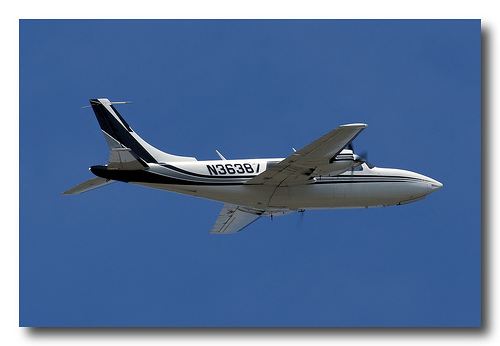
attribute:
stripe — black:
[148, 180, 411, 187]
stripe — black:
[162, 156, 419, 178]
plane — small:
[62, 95, 447, 239]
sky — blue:
[157, 47, 442, 108]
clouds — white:
[22, 19, 479, 327]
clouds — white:
[101, 257, 238, 334]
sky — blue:
[323, 62, 425, 106]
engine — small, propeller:
[280, 185, 313, 222]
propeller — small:
[344, 142, 369, 178]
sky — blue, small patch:
[21, 22, 483, 325]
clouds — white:
[393, 85, 457, 145]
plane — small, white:
[69, 85, 444, 262]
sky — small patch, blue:
[22, 22, 493, 103]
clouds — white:
[150, 65, 222, 86]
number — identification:
[202, 156, 263, 180]